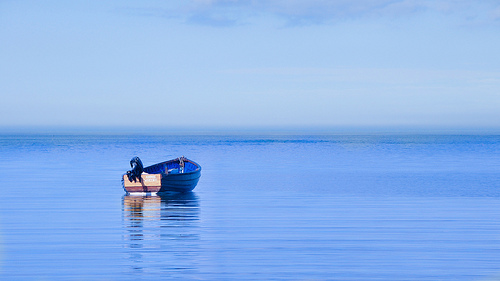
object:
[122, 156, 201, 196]
boat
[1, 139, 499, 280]
water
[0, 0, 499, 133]
sky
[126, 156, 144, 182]
engine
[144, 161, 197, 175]
shadow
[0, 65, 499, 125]
cloud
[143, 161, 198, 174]
interior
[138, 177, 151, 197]
shadow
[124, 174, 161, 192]
stern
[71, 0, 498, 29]
cloud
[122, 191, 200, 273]
reflection